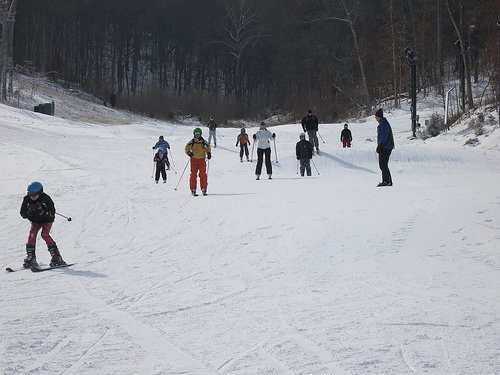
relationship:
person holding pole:
[19, 182, 64, 265] [41, 203, 72, 223]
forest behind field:
[40, 16, 459, 139] [9, 122, 495, 367]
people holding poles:
[0, 99, 402, 274] [243, 134, 261, 159]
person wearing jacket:
[289, 130, 324, 177] [296, 138, 315, 163]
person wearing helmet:
[19, 182, 64, 265] [25, 179, 44, 197]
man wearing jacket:
[374, 107, 394, 185] [376, 117, 394, 151]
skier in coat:
[191, 136, 226, 189] [183, 134, 217, 164]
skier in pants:
[191, 136, 226, 189] [186, 152, 209, 193]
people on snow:
[0, 99, 402, 274] [219, 224, 395, 344]